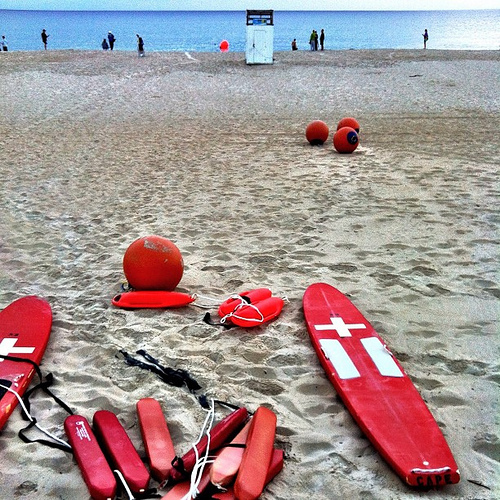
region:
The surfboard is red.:
[295, 276, 462, 488]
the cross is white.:
[311, 316, 367, 338]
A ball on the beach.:
[117, 233, 182, 290]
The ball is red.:
[121, 231, 184, 290]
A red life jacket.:
[211, 279, 285, 346]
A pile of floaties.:
[62, 399, 284, 498]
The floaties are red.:
[54, 402, 289, 499]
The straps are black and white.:
[1, 348, 61, 449]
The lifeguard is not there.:
[248, 5, 273, 70]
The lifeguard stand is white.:
[245, 8, 269, 61]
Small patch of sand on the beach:
[285, 217, 310, 242]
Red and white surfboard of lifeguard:
[295, 275, 460, 485]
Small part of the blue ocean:
[370, 25, 385, 37]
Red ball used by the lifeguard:
[305, 117, 330, 142]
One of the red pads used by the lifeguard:
[127, 395, 177, 465]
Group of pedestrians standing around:
[305, 27, 326, 57]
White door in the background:
[252, 28, 267, 64]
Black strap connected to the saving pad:
[130, 345, 205, 390]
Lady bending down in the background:
[98, 36, 108, 51]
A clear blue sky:
[131, 1, 146, 9]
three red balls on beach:
[299, 112, 366, 160]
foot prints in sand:
[348, 239, 454, 293]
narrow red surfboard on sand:
[293, 274, 457, 486]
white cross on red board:
[309, 307, 369, 349]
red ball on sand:
[111, 224, 192, 304]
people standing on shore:
[290, 23, 432, 61]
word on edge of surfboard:
[399, 468, 466, 494]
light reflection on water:
[430, 18, 496, 60]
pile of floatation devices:
[68, 400, 290, 497]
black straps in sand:
[118, 346, 224, 407]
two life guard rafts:
[1, 261, 473, 488]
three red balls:
[275, 104, 382, 164]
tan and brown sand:
[6, 32, 498, 459]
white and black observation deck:
[241, 5, 298, 76]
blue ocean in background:
[3, 5, 498, 57]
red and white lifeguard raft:
[272, 260, 496, 498]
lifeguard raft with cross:
[267, 254, 478, 488]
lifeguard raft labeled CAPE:
[284, 254, 486, 491]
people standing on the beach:
[21, 20, 179, 60]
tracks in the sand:
[15, 55, 157, 159]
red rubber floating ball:
[123, 233, 186, 290]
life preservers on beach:
[63, 395, 286, 495]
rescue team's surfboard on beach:
[302, 280, 461, 492]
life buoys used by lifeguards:
[216, 285, 286, 327]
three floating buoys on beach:
[305, 115, 362, 153]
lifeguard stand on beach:
[242, 7, 278, 67]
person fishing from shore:
[421, 26, 428, 46]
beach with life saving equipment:
[3, 48, 499, 495]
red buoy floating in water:
[218, 39, 230, 49]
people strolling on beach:
[98, 29, 148, 56]